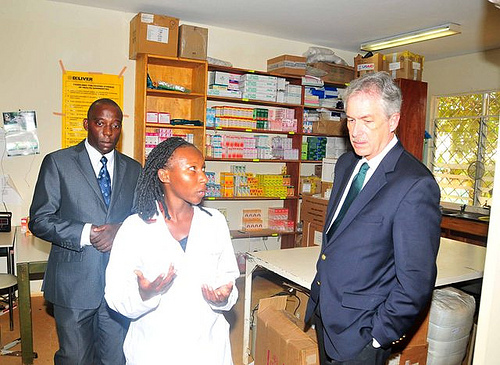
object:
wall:
[4, 2, 134, 227]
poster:
[0, 110, 41, 157]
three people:
[29, 70, 439, 364]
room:
[1, 1, 498, 363]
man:
[27, 98, 151, 363]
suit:
[25, 140, 142, 362]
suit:
[300, 141, 440, 363]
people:
[98, 134, 236, 365]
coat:
[102, 202, 239, 365]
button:
[319, 254, 326, 260]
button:
[313, 280, 320, 285]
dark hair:
[131, 136, 184, 219]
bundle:
[430, 288, 477, 364]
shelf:
[146, 89, 201, 97]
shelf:
[142, 115, 202, 132]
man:
[300, 71, 441, 362]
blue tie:
[323, 160, 375, 247]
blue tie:
[95, 154, 115, 207]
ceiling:
[118, 29, 354, 104]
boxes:
[147, 112, 159, 124]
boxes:
[380, 51, 425, 79]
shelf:
[141, 94, 205, 127]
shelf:
[210, 98, 295, 111]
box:
[250, 291, 320, 363]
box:
[129, 11, 181, 62]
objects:
[209, 69, 300, 103]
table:
[243, 232, 488, 365]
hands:
[88, 216, 117, 252]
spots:
[101, 178, 111, 192]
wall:
[2, 73, 49, 191]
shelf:
[135, 51, 208, 66]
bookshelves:
[133, 54, 298, 275]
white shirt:
[104, 208, 240, 365]